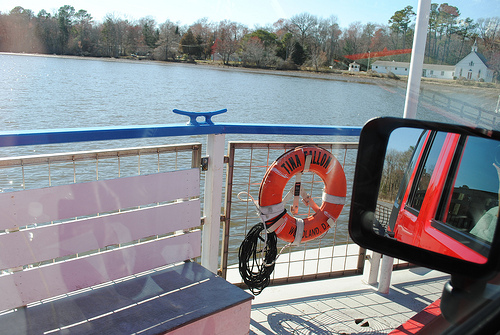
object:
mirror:
[347, 116, 499, 283]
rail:
[1, 108, 362, 148]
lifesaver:
[256, 146, 347, 245]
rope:
[239, 222, 277, 295]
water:
[0, 53, 499, 270]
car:
[347, 116, 498, 335]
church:
[453, 36, 495, 84]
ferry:
[1, 109, 497, 335]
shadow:
[249, 274, 449, 334]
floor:
[227, 242, 451, 334]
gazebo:
[347, 60, 360, 73]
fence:
[1, 166, 258, 334]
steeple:
[472, 36, 479, 52]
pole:
[401, 1, 432, 120]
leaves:
[243, 32, 250, 40]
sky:
[1, 0, 499, 42]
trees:
[1, 3, 499, 68]